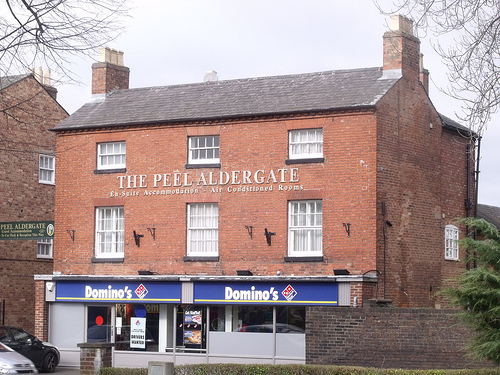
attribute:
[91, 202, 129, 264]
curtains — white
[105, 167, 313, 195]
letters — white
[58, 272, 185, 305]
sign — blue, white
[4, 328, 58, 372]
car — parked, black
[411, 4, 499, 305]
tree — tall, bare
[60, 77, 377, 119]
roof — shingled, slate, gray, slated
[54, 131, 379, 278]
facade — brick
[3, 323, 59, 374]
cars — small, parked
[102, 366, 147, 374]
bush — green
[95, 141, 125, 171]
curtains — white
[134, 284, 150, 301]
logo — red, blue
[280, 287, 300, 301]
logo — red, blue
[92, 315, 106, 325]
spot — red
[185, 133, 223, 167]
window — white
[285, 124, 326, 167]
window — white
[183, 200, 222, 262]
window — white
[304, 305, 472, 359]
wall — brick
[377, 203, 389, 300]
cord — black, electrical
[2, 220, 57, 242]
sign — green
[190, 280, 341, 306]
sign — blue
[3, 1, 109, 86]
tree — bare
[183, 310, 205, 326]
logo — red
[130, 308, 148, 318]
logo — blue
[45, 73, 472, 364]
building — red, brick, red brick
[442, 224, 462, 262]
curtains — white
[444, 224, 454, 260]
mullions — white